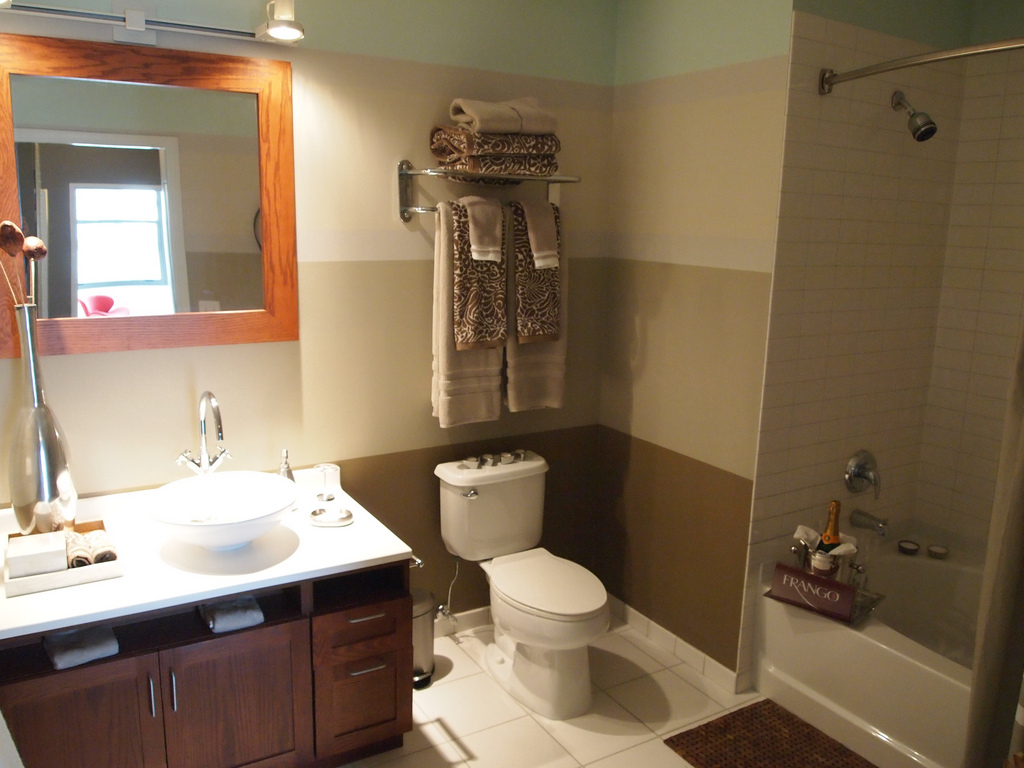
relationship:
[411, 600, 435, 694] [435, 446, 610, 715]
trash by toilet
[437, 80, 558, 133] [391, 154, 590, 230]
towel stacked on top of rack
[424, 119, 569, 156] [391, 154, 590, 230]
towel stacked on top of rack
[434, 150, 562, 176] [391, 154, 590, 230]
towel stacked on top of rack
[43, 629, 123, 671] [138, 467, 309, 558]
towel underneath sink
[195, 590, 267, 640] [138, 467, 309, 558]
towel underneath sink